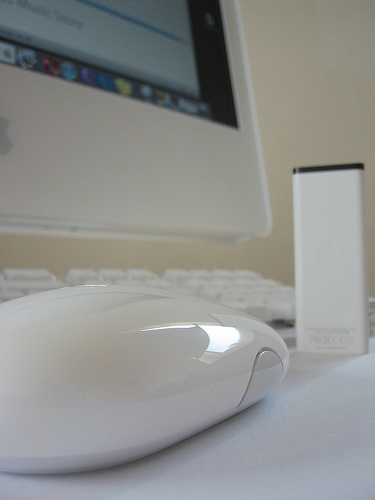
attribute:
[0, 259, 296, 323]
keyboard — white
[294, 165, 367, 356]
box — white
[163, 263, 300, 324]
keypad — white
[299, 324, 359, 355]
macintosh — icon, app, preview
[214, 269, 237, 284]
key — white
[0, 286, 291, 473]
mouse — shiny, white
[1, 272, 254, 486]
mouse — grey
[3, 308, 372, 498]
desk — plain, white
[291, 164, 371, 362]
cylinder — white, electric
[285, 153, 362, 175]
top — black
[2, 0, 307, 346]
imac — white, early 2000s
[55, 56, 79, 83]
app — safari, macintosh, icon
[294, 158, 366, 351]
remote — white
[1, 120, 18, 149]
logo — computer, apple macintosh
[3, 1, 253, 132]
screen — white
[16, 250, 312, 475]
mouse — white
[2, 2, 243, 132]
macintosh window — safari app